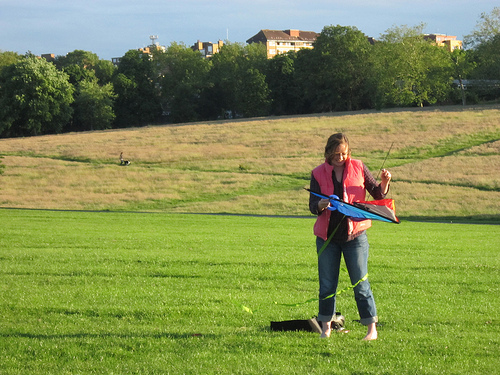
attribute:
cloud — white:
[15, 9, 99, 36]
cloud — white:
[103, 5, 353, 33]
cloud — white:
[356, 1, 498, 17]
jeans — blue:
[314, 238, 376, 325]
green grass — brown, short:
[0, 206, 498, 373]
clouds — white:
[129, 13, 202, 40]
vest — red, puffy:
[311, 155, 374, 240]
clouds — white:
[50, 7, 120, 39]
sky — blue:
[15, 7, 465, 55]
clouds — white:
[93, 12, 143, 37]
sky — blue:
[150, 7, 282, 49]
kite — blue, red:
[301, 180, 401, 233]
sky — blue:
[0, 0, 498, 68]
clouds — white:
[102, 9, 241, 36]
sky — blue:
[2, 2, 494, 51]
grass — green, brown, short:
[59, 225, 164, 313]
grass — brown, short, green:
[3, 207, 278, 372]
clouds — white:
[218, 2, 346, 23]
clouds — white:
[2, 1, 498, 59]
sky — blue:
[2, 2, 499, 61]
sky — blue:
[0, 0, 498, 56]